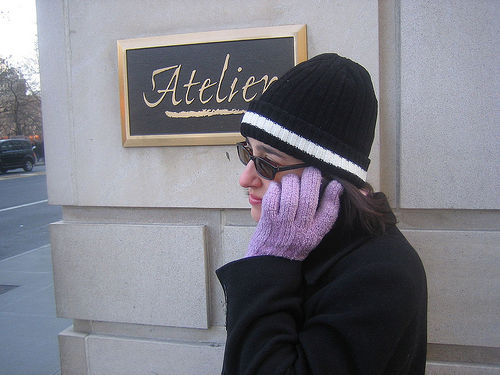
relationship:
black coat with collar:
[205, 194, 435, 374] [319, 191, 402, 242]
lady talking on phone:
[215, 52, 427, 375] [310, 175, 331, 213]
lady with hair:
[215, 52, 427, 375] [317, 179, 389, 239]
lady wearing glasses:
[215, 52, 427, 375] [236, 141, 311, 181]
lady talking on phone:
[215, 52, 427, 375] [319, 173, 330, 198]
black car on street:
[0, 135, 37, 174] [3, 162, 64, 372]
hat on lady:
[237, 50, 382, 187] [215, 52, 427, 375]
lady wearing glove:
[215, 52, 427, 375] [250, 162, 344, 258]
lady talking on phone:
[215, 52, 427, 375] [299, 170, 337, 240]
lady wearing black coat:
[215, 52, 427, 375] [214, 191, 427, 374]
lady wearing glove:
[215, 52, 427, 375] [245, 166, 342, 254]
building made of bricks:
[37, 3, 499, 372] [37, 0, 397, 207]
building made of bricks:
[37, 3, 499, 372] [48, 219, 223, 332]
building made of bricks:
[37, 3, 499, 372] [57, 328, 227, 373]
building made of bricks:
[37, 3, 499, 372] [399, 1, 499, 212]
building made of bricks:
[37, 3, 499, 372] [400, 229, 498, 351]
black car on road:
[0, 135, 37, 177] [0, 162, 63, 262]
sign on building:
[115, 23, 309, 147] [37, 3, 499, 372]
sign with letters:
[115, 23, 309, 147] [141, 52, 278, 108]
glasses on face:
[234, 137, 311, 177] [178, 64, 447, 339]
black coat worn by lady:
[214, 191, 427, 374] [215, 52, 428, 373]